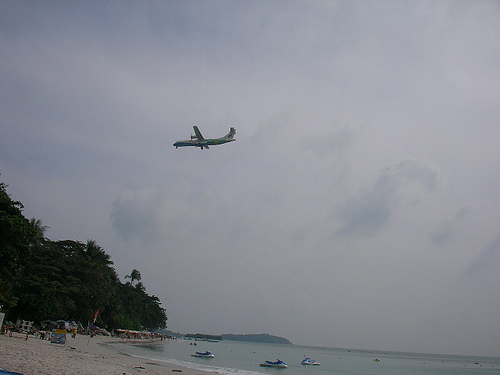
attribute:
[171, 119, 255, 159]
plane — flying, white, sky, big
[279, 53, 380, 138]
sky — cloudy, dark, black, blue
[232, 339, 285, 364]
water — blue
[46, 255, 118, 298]
trees — green